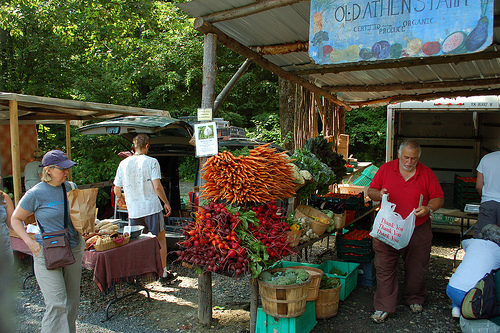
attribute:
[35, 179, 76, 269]
bag — brown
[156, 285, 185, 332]
ground — dirt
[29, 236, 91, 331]
pants — khaki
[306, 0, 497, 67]
sign — worn, hand drawn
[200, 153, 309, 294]
vegetables — different, variety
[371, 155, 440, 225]
shirt — red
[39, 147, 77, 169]
hat — blue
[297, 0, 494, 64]
sign — blue 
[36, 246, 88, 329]
pants — gray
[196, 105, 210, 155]
sign — white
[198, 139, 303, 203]
carrots — huge, pile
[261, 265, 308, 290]
vegetable — green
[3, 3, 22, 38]
leaves — tree, green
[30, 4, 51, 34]
leaves — tree, green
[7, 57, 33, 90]
leaves — tree, green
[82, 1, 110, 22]
leaves — tree, green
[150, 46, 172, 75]
leaves — tree, green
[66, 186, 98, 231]
bag — brown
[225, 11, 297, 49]
metal roof — corrugated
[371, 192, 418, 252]
bag — plastic 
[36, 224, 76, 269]
purse — brown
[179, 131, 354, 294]
vegetables — piles 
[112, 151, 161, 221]
t-shirt — white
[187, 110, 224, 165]
sign — white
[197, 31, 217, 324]
post — wooden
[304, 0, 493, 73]
sign — blue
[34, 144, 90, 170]
cap — blue